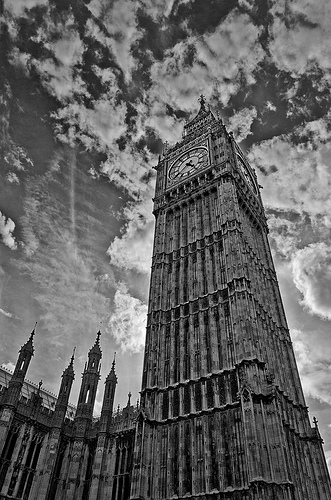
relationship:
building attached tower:
[2, 330, 330, 498] [136, 84, 309, 407]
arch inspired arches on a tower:
[209, 183, 217, 203] [141, 98, 328, 489]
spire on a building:
[7, 321, 37, 410] [1, 94, 330, 498]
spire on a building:
[53, 346, 75, 429] [1, 94, 330, 498]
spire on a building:
[73, 321, 102, 434] [1, 94, 330, 498]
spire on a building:
[99, 351, 118, 436] [1, 94, 330, 498]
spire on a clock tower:
[186, 89, 213, 115] [139, 88, 314, 464]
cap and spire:
[86, 342, 103, 356] [88, 345, 103, 354]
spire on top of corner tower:
[88, 345, 103, 354] [74, 324, 100, 422]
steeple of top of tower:
[183, 90, 227, 143] [160, 127, 249, 381]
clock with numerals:
[167, 145, 209, 181] [168, 146, 205, 179]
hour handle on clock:
[187, 161, 197, 170] [167, 145, 209, 181]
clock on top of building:
[167, 145, 209, 181] [137, 95, 306, 497]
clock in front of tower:
[162, 142, 218, 181] [151, 116, 288, 498]